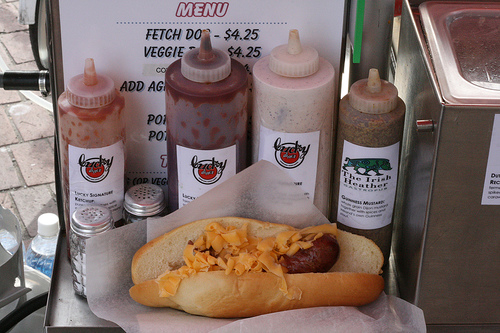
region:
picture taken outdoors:
[13, 6, 496, 326]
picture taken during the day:
[4, 1, 492, 329]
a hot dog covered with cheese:
[201, 224, 329, 266]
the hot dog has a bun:
[121, 203, 349, 327]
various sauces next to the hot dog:
[70, 37, 448, 212]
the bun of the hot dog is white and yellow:
[181, 277, 388, 307]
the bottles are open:
[80, 50, 397, 124]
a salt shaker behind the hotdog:
[74, 213, 136, 325]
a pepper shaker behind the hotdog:
[131, 183, 156, 227]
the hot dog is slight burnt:
[294, 241, 332, 268]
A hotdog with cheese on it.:
[128, 214, 383, 316]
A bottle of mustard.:
[333, 64, 407, 265]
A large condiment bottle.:
[251, 33, 336, 230]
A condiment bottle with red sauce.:
[164, 33, 251, 213]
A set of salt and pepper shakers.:
[72, 180, 164, 299]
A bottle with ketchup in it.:
[58, 53, 125, 268]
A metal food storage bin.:
[389, 0, 498, 327]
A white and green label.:
[336, 142, 402, 229]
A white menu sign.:
[61, 2, 346, 202]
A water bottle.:
[27, 210, 64, 280]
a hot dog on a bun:
[141, 209, 378, 316]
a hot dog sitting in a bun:
[133, 209, 374, 316]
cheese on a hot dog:
[129, 169, 407, 299]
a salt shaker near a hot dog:
[50, 175, 152, 303]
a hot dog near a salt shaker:
[108, 183, 387, 322]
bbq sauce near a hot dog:
[136, 26, 278, 221]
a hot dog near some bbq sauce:
[136, 57, 379, 326]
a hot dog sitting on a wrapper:
[97, 156, 403, 327]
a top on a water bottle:
[18, 210, 63, 251]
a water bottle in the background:
[24, 212, 66, 277]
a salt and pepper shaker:
[68, 181, 163, 298]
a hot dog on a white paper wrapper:
[131, 217, 385, 316]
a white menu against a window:
[61, 2, 346, 202]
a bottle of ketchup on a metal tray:
[56, 58, 127, 265]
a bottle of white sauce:
[249, 28, 334, 218]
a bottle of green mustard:
[334, 67, 406, 273]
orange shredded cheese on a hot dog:
[161, 223, 336, 289]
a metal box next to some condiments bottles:
[397, 0, 499, 332]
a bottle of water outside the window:
[26, 212, 59, 275]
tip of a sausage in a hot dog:
[278, 228, 339, 274]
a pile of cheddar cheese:
[161, 225, 306, 292]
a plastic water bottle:
[22, 212, 73, 317]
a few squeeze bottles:
[158, 24, 406, 275]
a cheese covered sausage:
[181, 222, 342, 286]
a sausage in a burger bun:
[131, 219, 412, 325]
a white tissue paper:
[79, 159, 429, 331]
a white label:
[166, 140, 239, 211]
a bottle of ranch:
[249, 25, 340, 225]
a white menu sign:
[61, 0, 351, 212]